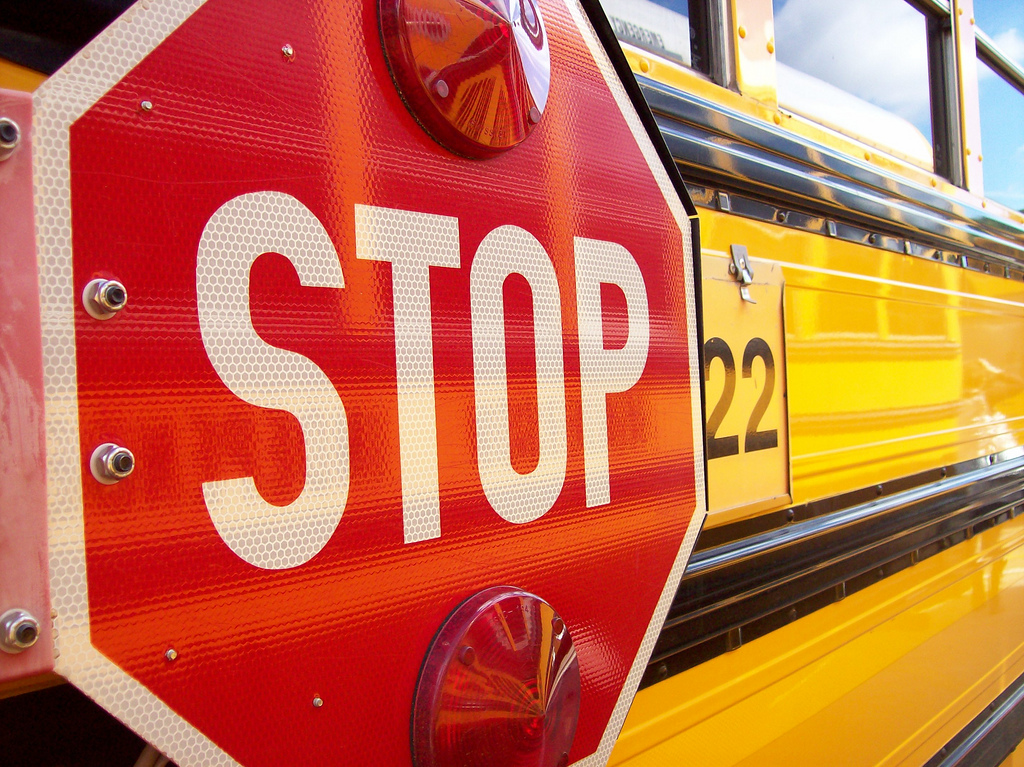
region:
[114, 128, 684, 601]
a red and white sign on a school bus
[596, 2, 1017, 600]
reflection of another bus in window and side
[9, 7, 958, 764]
red stop sign on a yellow bus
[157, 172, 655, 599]
a stop sign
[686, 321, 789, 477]
black number 22 on a yellow school bus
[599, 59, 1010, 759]
the side of a school bus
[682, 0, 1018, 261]
windows on the side of a school bus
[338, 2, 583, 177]
red lights on the stop sign of a school bus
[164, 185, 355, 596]
a white letter S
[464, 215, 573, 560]
a white letter O on a red stop sign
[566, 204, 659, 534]
a white letter P on a red stop sign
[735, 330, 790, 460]
a black number 2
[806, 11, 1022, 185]
blue sky and white clouds reflecting in the windows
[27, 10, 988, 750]
Stop sign in school bus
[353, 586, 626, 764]
Signal lamp on stop sign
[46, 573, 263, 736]
Reflecting paint on Stop sign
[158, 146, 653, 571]
Word STOP on stop sign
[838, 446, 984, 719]
Yellow and black paint on school bus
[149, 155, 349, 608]
Letter S in stop sign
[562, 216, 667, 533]
Letter P in stop sign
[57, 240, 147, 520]
Bolts that fasten sign to bus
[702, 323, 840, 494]
Number on the school bus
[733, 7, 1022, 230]
School bus windows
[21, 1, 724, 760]
red stop sign with unlit lights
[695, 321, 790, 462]
black letters on yellow background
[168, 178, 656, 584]
white letters saying STOP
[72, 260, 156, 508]
bolts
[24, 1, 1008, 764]
stop sign on side of yellow bus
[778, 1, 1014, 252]
windows on side of bus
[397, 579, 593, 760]
unlit red light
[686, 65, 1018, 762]
side of a yellow bus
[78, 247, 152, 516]
double bolts holding stop sign on bus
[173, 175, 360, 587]
large letter S on red background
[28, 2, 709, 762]
Stop sign is reflective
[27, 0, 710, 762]
stop sign is red and white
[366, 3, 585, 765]
two red flashing lights on the stop sign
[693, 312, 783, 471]
Bus has number 22 on the side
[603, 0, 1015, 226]
bus has windows on the side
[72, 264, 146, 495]
Bolts hold the stop sign onto the bus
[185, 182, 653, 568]
the word stop is painted in white on the sign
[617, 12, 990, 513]
A second bus is reflected in this bus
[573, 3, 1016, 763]
The bus is yellow and black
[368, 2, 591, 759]
The red flashing lights are off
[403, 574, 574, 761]
red safety reflector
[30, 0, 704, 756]
STOP sign on side of bus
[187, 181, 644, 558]
white reflective block letters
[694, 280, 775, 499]
bus number 22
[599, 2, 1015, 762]
yellow school bus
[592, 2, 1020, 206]
sliding school bus windows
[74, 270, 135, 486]
metal bolts attached to bus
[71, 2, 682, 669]
STOP sign reflecting opposite bus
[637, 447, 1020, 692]
black strip on side of bus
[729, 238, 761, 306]
latch securing bus number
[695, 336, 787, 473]
bus number on the side of the bus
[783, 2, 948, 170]
tinted black windows on bus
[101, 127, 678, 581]
stop sign on the side of a bus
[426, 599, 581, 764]
lights on the stop sign of a bus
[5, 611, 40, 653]
large screws on the side of a bus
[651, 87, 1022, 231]
black paneling on the side of a bus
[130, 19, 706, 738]
red and white stop sign on a bus